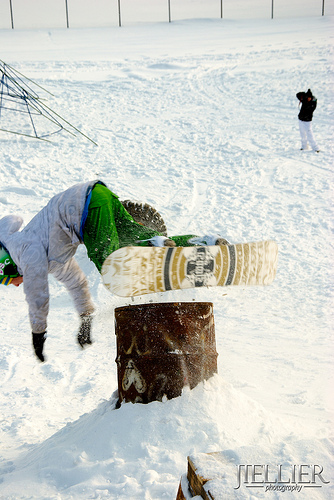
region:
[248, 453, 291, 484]
part of a graphic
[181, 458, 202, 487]
edge of a box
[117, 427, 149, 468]
part of a shade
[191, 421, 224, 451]
part of a snow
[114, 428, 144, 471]
edge of a now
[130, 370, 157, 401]
edge of a love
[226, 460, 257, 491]
part of a letter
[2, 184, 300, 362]
Person doing flips while snowboarding.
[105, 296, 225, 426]
Rusty steel drum partly buried in snow.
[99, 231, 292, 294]
Bottom of snowboard attached to person's feet.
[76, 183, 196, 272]
Person wearing green pants.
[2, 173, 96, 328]
Person wearing gray print jacket.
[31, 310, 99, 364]
Person wearing black gloves.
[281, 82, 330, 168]
Person taking pictures of snowboarder.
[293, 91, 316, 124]
Person wearing black jacket.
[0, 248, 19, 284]
Snowboarder wearing green cap.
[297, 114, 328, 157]
Person taking picture wearing white pants.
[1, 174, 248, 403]
person on snowboard jumping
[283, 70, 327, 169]
person in background taking photograph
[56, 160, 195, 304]
person wearing green snow pants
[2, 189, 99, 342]
person wearing white jacket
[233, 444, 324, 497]
white lettering in bottom right hand corner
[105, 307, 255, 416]
metal rusted garbage can with white writing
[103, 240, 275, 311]
white snowboard with blue and yellow design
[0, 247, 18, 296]
person wearing green hat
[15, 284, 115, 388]
person wearing black gloves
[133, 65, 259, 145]
tracks in white snow in photograph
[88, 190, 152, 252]
green pants on person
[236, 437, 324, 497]
name on bottom right corner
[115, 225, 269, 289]
snowboard on the man's legs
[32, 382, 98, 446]
white snow on the ground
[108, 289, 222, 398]
brown can on the ground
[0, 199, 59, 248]
hood of the jacket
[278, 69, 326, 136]
person in the background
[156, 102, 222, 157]
tracks in the snow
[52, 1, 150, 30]
fence in the background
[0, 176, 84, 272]
gray sweater on person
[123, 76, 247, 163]
The snow is white.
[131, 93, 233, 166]
The snow is rough looking.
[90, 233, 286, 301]
A snowboard.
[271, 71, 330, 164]
A person is in the background.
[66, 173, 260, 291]
The person is wearing green pants.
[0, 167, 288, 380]
The person is snowboarding.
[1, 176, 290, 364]
The person is making a jump.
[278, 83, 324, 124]
The person is wearing a black top.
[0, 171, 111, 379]
The person is wearing a white top.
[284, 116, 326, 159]
The person is wearing white pants.